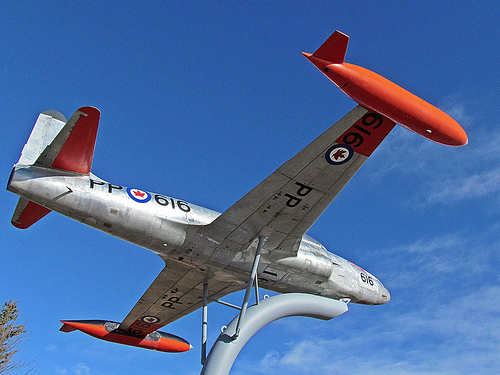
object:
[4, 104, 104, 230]
tail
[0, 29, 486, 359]
plane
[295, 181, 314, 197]
letter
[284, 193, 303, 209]
letter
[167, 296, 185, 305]
letter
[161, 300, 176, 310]
letter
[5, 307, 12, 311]
leaf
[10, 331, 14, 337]
leaf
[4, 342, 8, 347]
leaf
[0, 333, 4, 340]
leaf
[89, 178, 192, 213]
writing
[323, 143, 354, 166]
writing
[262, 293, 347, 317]
beam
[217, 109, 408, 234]
wing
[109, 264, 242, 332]
wing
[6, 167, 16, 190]
exhaust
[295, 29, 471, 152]
side engine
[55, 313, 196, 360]
side engine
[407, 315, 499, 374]
cloud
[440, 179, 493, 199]
cloud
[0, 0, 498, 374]
sky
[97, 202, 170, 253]
belly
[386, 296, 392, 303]
tip